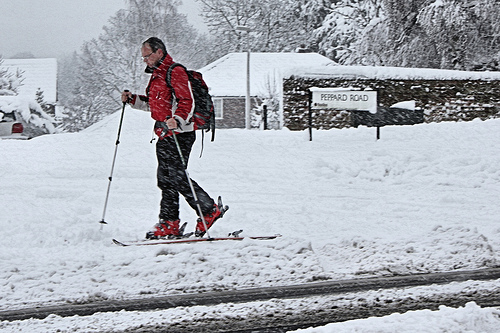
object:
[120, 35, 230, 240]
man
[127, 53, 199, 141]
jacket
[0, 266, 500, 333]
cement road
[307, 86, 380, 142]
sign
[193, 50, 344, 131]
house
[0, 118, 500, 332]
ground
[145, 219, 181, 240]
boots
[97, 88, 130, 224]
ski pole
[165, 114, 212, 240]
ski pole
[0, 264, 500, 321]
tracks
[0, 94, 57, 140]
car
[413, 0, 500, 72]
trees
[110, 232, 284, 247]
skis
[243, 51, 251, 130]
pole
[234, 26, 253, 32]
light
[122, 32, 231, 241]
snow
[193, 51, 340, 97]
roof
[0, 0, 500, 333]
snow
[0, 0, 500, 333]
outside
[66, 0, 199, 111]
trees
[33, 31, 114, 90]
wind